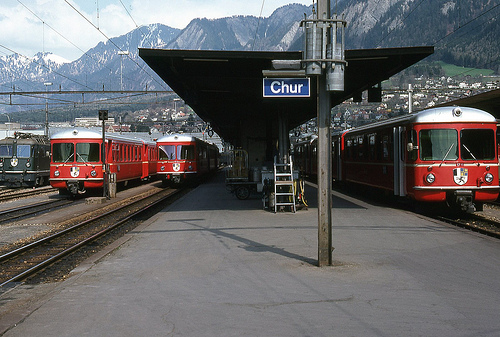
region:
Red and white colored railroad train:
[50, 128, 152, 191]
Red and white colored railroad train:
[155, 133, 218, 185]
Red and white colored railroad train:
[335, 105, 497, 212]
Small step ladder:
[269, 150, 300, 217]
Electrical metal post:
[298, 0, 348, 268]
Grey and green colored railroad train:
[0, 127, 47, 187]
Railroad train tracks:
[0, 193, 177, 290]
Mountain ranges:
[0, 22, 160, 97]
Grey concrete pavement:
[75, 267, 490, 333]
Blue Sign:
[260, 73, 314, 97]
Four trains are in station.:
[3, 96, 498, 231]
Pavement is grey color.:
[147, 238, 297, 321]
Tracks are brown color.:
[13, 198, 87, 260]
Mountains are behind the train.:
[23, 28, 490, 98]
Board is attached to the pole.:
[247, 58, 342, 155]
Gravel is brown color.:
[0, 188, 102, 272]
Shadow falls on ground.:
[144, 170, 407, 315]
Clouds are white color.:
[8, 11, 117, 46]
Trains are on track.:
[9, 120, 497, 240]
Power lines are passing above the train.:
[11, 1, 208, 128]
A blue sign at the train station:
[254, 69, 318, 107]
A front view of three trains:
[41, 93, 498, 232]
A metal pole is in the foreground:
[301, 1, 348, 278]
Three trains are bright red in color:
[44, 93, 499, 234]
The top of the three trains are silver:
[46, 98, 497, 146]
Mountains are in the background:
[3, 2, 498, 89]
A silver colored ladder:
[264, 148, 306, 223]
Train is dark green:
[1, 125, 48, 197]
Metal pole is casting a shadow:
[158, 195, 329, 284]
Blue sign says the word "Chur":
[259, 68, 316, 103]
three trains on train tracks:
[1, 120, 216, 203]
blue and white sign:
[255, 67, 319, 107]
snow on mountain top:
[12, 37, 123, 86]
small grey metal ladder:
[263, 145, 302, 231]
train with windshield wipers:
[43, 122, 114, 190]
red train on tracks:
[46, 127, 147, 193]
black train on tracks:
[2, 127, 47, 185]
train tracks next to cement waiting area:
[20, 199, 106, 268]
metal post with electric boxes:
[305, 2, 344, 279]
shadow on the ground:
[158, 200, 311, 320]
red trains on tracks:
[35, 121, 226, 195]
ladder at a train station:
[267, 152, 303, 216]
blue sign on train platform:
[254, 69, 319, 107]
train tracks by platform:
[5, 192, 74, 272]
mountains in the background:
[0, 22, 134, 99]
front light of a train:
[414, 167, 445, 189]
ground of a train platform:
[92, 280, 497, 325]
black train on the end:
[0, 126, 52, 198]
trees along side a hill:
[447, 27, 496, 77]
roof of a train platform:
[132, 34, 257, 91]